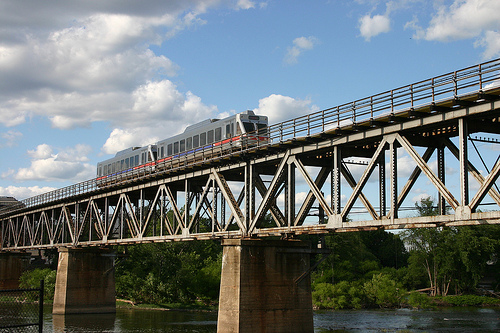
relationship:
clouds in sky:
[1, 0, 206, 188] [8, 12, 482, 146]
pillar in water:
[215, 236, 318, 328] [6, 301, 498, 330]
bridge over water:
[5, 67, 489, 240] [6, 301, 498, 330]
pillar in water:
[52, 248, 120, 308] [6, 301, 498, 330]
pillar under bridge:
[215, 236, 318, 328] [5, 67, 489, 240]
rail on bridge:
[116, 60, 499, 155] [5, 67, 489, 240]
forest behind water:
[2, 217, 499, 308] [6, 301, 498, 330]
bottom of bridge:
[6, 220, 497, 248] [5, 67, 489, 240]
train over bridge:
[91, 107, 274, 194] [5, 67, 489, 240]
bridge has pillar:
[5, 67, 489, 240] [52, 248, 120, 308]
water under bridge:
[6, 301, 498, 330] [5, 67, 489, 240]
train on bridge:
[91, 107, 274, 194] [5, 67, 489, 240]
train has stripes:
[91, 107, 274, 194] [100, 139, 253, 183]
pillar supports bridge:
[215, 236, 318, 328] [5, 67, 489, 240]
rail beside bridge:
[116, 60, 499, 155] [5, 67, 489, 240]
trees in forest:
[117, 245, 214, 301] [2, 217, 499, 308]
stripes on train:
[100, 139, 253, 183] [91, 107, 274, 194]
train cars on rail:
[91, 107, 274, 194] [116, 60, 499, 155]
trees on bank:
[117, 245, 214, 301] [10, 280, 500, 306]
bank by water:
[10, 280, 500, 306] [6, 301, 498, 330]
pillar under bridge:
[52, 248, 120, 308] [5, 67, 489, 240]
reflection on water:
[104, 305, 212, 328] [6, 301, 498, 330]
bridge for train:
[5, 67, 489, 240] [91, 107, 274, 194]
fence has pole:
[0, 276, 46, 331] [37, 280, 47, 331]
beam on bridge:
[304, 123, 490, 228] [5, 67, 489, 240]